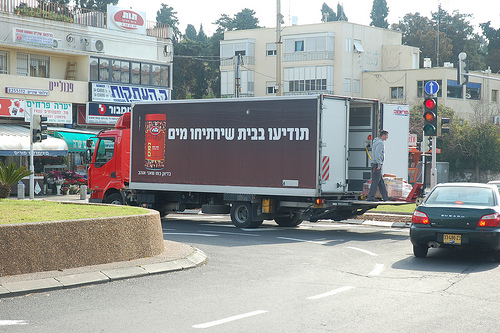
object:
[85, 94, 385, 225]
truck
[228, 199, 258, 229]
tires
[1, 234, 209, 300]
sidewalk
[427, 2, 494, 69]
trees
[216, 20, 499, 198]
buildings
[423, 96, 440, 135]
lights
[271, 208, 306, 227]
wheels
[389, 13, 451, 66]
trees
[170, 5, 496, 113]
distance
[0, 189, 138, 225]
grass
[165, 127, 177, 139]
writing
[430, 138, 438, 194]
post